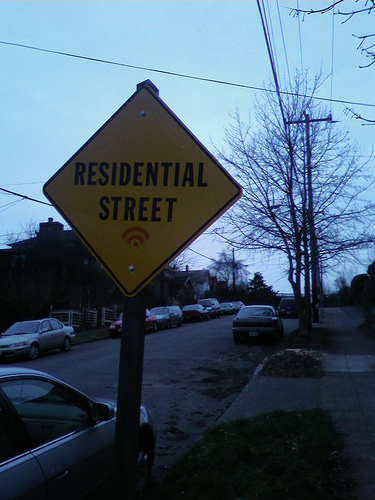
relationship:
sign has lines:
[41, 84, 243, 295] [119, 228, 148, 249]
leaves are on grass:
[263, 348, 324, 377] [256, 354, 324, 378]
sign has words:
[41, 84, 243, 295] [75, 160, 209, 220]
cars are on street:
[1, 301, 244, 361] [1, 314, 299, 478]